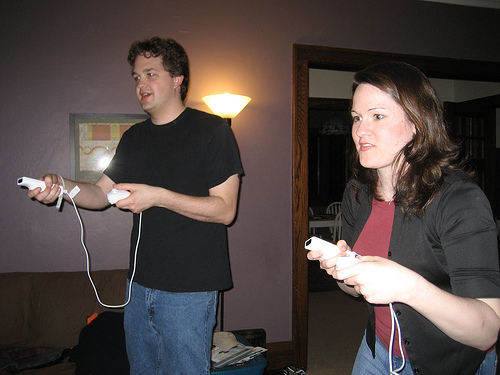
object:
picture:
[69, 111, 149, 186]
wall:
[0, 2, 499, 342]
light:
[201, 93, 251, 120]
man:
[26, 39, 246, 374]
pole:
[217, 293, 225, 332]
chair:
[330, 213, 342, 248]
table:
[308, 210, 343, 242]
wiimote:
[16, 175, 65, 208]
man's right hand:
[25, 173, 69, 205]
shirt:
[352, 196, 395, 360]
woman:
[306, 62, 499, 375]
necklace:
[376, 178, 400, 208]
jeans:
[120, 276, 220, 374]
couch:
[0, 268, 140, 374]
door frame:
[290, 44, 499, 374]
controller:
[300, 236, 407, 373]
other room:
[303, 96, 498, 374]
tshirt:
[102, 107, 247, 293]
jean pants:
[350, 328, 499, 374]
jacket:
[332, 167, 500, 374]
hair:
[344, 60, 480, 224]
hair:
[126, 37, 190, 102]